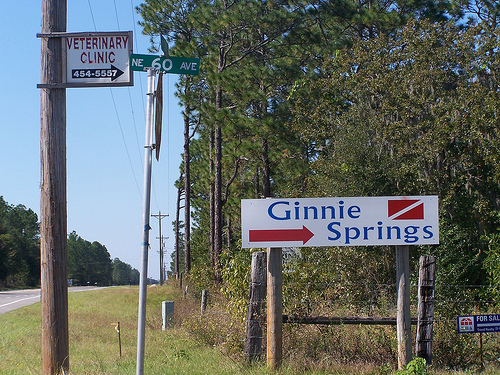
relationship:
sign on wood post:
[238, 188, 449, 269] [264, 243, 289, 362]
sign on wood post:
[238, 188, 449, 269] [399, 243, 412, 373]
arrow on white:
[241, 226, 314, 247] [227, 180, 447, 266]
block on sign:
[384, 194, 431, 225] [230, 180, 450, 259]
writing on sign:
[271, 200, 361, 220] [237, 188, 453, 262]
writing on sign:
[325, 213, 436, 247] [237, 189, 437, 252]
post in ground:
[412, 245, 442, 365] [401, 347, 458, 371]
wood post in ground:
[240, 245, 264, 359] [230, 358, 260, 373]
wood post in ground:
[259, 248, 286, 366] [252, 357, 292, 373]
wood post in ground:
[393, 243, 415, 362] [382, 360, 442, 373]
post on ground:
[133, 71, 165, 356] [121, 358, 154, 373]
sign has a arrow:
[238, 196, 441, 246] [248, 224, 314, 245]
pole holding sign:
[266, 247, 282, 372] [241, 178, 437, 245]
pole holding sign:
[396, 246, 411, 368] [241, 178, 437, 245]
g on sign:
[264, 196, 294, 225] [232, 193, 439, 245]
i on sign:
[290, 198, 304, 227] [237, 189, 437, 252]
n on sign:
[302, 202, 322, 227] [237, 189, 437, 252]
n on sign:
[322, 200, 340, 220] [241, 198, 441, 250]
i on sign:
[333, 196, 347, 217] [237, 189, 437, 252]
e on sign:
[350, 200, 360, 220] [237, 189, 437, 252]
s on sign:
[324, 225, 338, 239] [235, 200, 436, 247]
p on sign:
[346, 222, 355, 242] [237, 189, 437, 252]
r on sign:
[357, 216, 382, 243] [237, 189, 437, 252]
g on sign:
[399, 224, 419, 247] [241, 198, 441, 250]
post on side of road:
[242, 195, 441, 248] [1, 262, 75, 318]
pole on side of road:
[33, 7, 82, 372] [1, 278, 95, 328]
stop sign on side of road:
[144, 71, 173, 163] [1, 269, 61, 336]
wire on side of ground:
[90, 14, 166, 241] [0, 286, 496, 374]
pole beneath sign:
[390, 253, 415, 367] [230, 180, 440, 254]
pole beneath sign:
[268, 242, 289, 372] [230, 180, 440, 254]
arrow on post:
[248, 224, 314, 245] [233, 184, 440, 256]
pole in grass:
[146, 209, 173, 283] [1, 271, 253, 371]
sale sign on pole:
[458, 315, 500, 333] [475, 334, 485, 372]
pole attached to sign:
[477, 334, 495, 372] [455, 314, 498, 334]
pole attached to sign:
[264, 247, 287, 372] [226, 187, 436, 248]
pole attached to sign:
[392, 248, 416, 368] [241, 198, 441, 250]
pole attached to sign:
[266, 247, 282, 372] [241, 198, 441, 250]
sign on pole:
[66, 30, 134, 90] [42, 4, 66, 373]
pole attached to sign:
[138, 64, 158, 373] [154, 73, 164, 153]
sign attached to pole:
[130, 51, 201, 77] [138, 64, 158, 373]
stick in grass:
[117, 322, 125, 363] [2, 287, 252, 373]